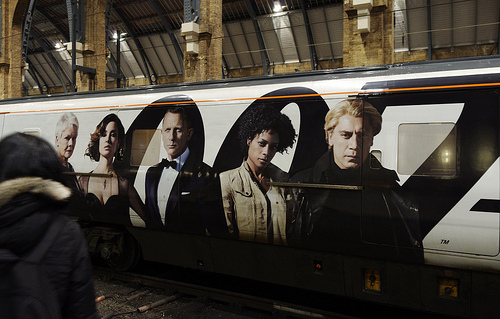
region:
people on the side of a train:
[44, 97, 464, 263]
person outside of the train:
[8, 123, 115, 315]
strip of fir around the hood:
[2, 170, 82, 207]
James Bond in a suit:
[139, 101, 233, 228]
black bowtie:
[157, 157, 177, 171]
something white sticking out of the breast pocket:
[179, 185, 194, 199]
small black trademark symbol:
[437, 230, 457, 250]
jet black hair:
[3, 130, 67, 182]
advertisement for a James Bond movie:
[32, 67, 499, 279]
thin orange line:
[165, 85, 412, 112]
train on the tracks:
[3, 74, 489, 263]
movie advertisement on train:
[44, 107, 470, 237]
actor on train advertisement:
[298, 97, 453, 253]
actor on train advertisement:
[220, 122, 293, 244]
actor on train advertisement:
[139, 112, 214, 236]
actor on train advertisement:
[77, 115, 146, 225]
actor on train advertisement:
[44, 111, 89, 187]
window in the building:
[307, 9, 333, 58]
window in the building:
[257, 18, 281, 60]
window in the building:
[231, 27, 253, 65]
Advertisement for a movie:
[94, 116, 438, 239]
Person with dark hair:
[7, 138, 62, 176]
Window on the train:
[397, 121, 454, 177]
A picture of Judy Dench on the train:
[56, 119, 78, 152]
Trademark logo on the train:
[437, 236, 454, 247]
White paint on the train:
[18, 116, 51, 129]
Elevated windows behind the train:
[226, 17, 339, 55]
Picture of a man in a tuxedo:
[148, 164, 224, 232]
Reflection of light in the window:
[436, 143, 453, 169]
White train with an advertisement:
[13, 66, 495, 222]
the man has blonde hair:
[334, 101, 379, 116]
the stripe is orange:
[203, 93, 235, 110]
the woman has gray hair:
[58, 114, 78, 126]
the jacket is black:
[8, 180, 104, 315]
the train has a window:
[393, 119, 462, 181]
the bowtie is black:
[157, 157, 182, 173]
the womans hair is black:
[257, 112, 278, 127]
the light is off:
[171, 17, 208, 59]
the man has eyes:
[161, 124, 186, 136]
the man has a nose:
[348, 134, 363, 151]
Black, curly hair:
[233, 101, 300, 154]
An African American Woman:
[222, 103, 299, 243]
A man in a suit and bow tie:
[141, 103, 230, 240]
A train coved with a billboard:
[0, 56, 499, 302]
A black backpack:
[0, 215, 66, 316]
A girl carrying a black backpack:
[0, 128, 101, 315]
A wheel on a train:
[83, 221, 143, 274]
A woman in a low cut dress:
[78, 113, 145, 222]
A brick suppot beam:
[180, 0, 227, 80]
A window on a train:
[394, 120, 461, 178]